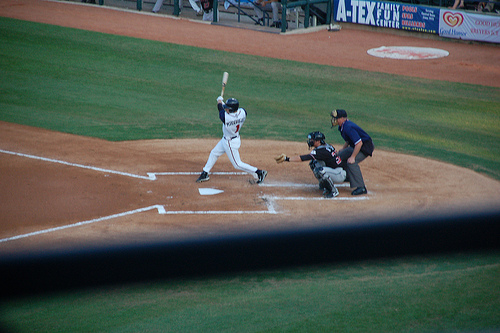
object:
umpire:
[329, 108, 374, 195]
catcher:
[273, 131, 347, 198]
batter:
[195, 96, 268, 184]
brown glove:
[273, 154, 289, 165]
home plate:
[198, 187, 225, 196]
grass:
[1, 17, 200, 126]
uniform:
[202, 102, 259, 172]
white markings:
[0, 146, 369, 243]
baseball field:
[0, 0, 499, 331]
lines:
[259, 183, 357, 188]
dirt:
[0, 121, 499, 248]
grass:
[401, 87, 458, 124]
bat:
[220, 71, 229, 97]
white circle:
[367, 46, 451, 61]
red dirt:
[1, 0, 499, 89]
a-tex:
[335, 0, 375, 25]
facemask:
[331, 108, 338, 128]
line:
[0, 147, 156, 183]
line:
[3, 195, 159, 246]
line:
[150, 171, 248, 175]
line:
[155, 202, 276, 214]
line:
[269, 196, 370, 201]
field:
[2, 0, 496, 332]